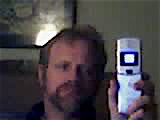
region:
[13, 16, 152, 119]
man holding a phone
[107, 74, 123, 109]
thumb on the side of the phone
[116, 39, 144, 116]
silver flip phone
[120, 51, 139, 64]
display on the front of the phone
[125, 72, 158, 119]
fingers wrapped around the phone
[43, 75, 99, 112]
hair on the face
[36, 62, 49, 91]
ear on the side of the head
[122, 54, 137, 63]
display is lit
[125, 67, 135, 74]
small black rectangle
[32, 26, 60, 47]
light glare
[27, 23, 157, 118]
this is a person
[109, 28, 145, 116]
this is a phone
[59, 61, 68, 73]
this is an eye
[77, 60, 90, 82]
this is an eye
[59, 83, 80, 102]
this is a mouth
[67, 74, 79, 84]
this is a nose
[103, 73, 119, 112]
this is a finger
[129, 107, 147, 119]
this is a finger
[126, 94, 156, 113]
this is a finger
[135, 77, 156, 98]
this is a finger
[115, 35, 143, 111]
the flip phone in hand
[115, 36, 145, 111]
the grey cell phone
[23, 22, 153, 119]
th man taking a selfie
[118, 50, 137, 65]
the screen on the phone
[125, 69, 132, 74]
the camera on the cell phone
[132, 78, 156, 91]
the finger holding the phone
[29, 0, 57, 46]
the light reflecting off the picture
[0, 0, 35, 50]
the picture on the wall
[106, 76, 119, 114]
the thumb of the man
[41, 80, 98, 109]
the beard on the face of the man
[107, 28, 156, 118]
hand holding a cell phone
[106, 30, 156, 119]
hand holding a mobile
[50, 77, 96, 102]
the mustache of a man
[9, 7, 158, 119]
a man taking a selfie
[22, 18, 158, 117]
a bearded man taking a selfie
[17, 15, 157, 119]
a bearded man photographing himself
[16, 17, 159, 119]
a man photographing himself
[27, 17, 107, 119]
man with a beard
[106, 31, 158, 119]
hand of a man holding a phone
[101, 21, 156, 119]
hand holding a phone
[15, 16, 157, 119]
a man holding a phone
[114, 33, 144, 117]
phone is color silver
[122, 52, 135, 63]
small screen over the phone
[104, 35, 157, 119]
a hand holding a phone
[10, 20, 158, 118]
man has a goatee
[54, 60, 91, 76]
eyes of a man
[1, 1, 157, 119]
the picture is blurry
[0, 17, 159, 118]
man is holding a phone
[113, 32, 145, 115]
a cell phone color gray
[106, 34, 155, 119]
fingers around a phone